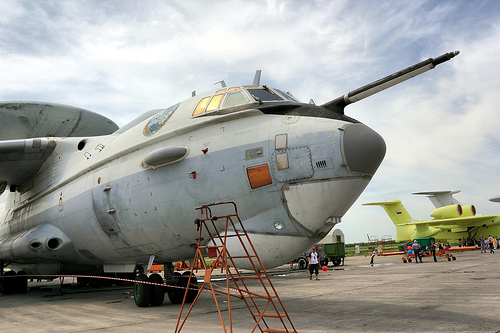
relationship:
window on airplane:
[205, 89, 233, 123] [50, 89, 470, 253]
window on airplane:
[188, 89, 220, 124] [28, 81, 360, 309]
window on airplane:
[231, 83, 287, 104] [94, 129, 354, 233]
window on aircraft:
[261, 83, 300, 107] [0, 48, 474, 292]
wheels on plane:
[145, 265, 208, 306] [86, 123, 373, 323]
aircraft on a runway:
[4, 30, 480, 289] [324, 275, 476, 329]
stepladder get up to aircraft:
[180, 203, 280, 331] [0, 48, 474, 292]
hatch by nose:
[248, 162, 268, 186] [294, 111, 400, 216]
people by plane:
[400, 234, 497, 262] [362, 186, 498, 255]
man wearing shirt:
[303, 244, 322, 282] [304, 251, 320, 265]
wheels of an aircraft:
[132, 260, 197, 314] [8, 40, 466, 307]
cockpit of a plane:
[199, 83, 308, 112] [2, 30, 463, 310]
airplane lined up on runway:
[364, 197, 500, 250] [4, 254, 494, 332]